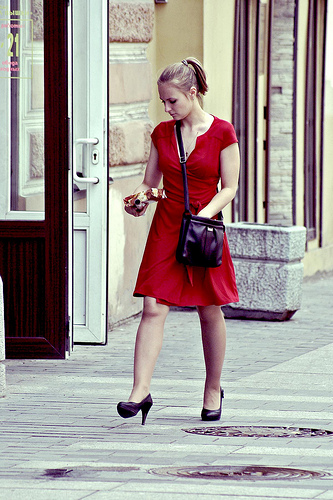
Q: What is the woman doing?
A: Walking.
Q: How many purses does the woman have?
A: One.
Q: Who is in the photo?
A: A woman.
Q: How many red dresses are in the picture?
A: One.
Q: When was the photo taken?
A: Daytime.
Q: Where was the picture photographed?
A: On a sidewalk.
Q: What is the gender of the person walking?
A: Female.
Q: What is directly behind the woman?
A: A planter.